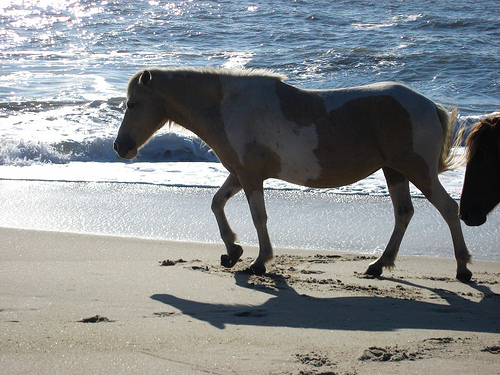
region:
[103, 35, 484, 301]
A brown and white pony walking on the beach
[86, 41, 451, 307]
The pony is walking near the ocean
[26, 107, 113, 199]
Waves crashing to shore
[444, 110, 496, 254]
This horse is brown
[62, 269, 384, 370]
The sand is very wet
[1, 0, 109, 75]
It is daytime in and sunny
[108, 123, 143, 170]
The pony's nose is black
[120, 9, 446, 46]
The water looks rough and choppy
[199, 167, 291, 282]
Front legs of the pony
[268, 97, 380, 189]
The belly of the pony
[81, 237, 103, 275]
Small patch of brown sand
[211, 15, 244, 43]
Small patch of blue ocean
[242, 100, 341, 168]
Brown and white skin of horse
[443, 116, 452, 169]
Golden tail of horse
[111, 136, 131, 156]
Black nose of horse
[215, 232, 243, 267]
Right front foot of horse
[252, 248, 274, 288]
Left front foot of horse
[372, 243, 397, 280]
Back right foot of horse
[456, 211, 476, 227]
Nose of the second horse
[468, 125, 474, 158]
Golden hair of horse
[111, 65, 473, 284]
tan and white horse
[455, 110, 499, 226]
brown head of horse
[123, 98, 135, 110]
large black eye of horse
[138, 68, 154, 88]
pointed ear of horse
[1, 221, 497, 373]
brown wet sand on beach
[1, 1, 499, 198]
wavy dark ocean water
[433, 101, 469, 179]
beige tail of horse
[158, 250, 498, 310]
tracks from horses in sand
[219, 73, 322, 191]
white spot on horse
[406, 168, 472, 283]
rear leg of tan horse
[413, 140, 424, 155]
back of a horse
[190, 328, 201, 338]
part of the shore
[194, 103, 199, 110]
neck of a horse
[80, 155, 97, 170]
part of a wave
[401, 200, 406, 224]
leg of a horse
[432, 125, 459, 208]
part of a tail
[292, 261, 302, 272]
part of a print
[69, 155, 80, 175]
part of the ocean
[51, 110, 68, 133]
part of the sea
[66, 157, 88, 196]
part of a lake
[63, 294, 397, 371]
The dirt on the beach is wet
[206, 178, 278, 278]
The front legs of the horse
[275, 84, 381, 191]
The stomach of the horse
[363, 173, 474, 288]
The back legs of the horse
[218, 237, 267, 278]
The feet of the horse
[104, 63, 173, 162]
The head of the horse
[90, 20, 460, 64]
The water on the beach is calm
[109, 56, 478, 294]
The horse is walking on the beach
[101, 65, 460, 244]
The horse is brown and beige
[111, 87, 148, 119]
The eye of the horse